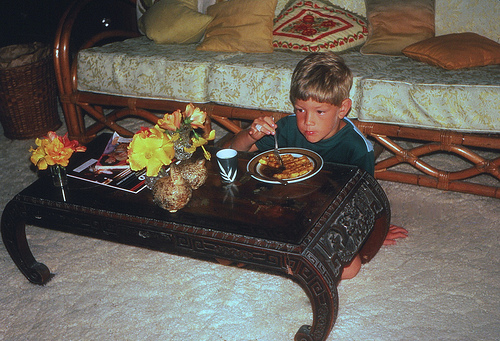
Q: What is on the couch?
A: Pillows.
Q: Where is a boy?
A: Sitting on floor.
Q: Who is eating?
A: A boy.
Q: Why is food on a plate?
A: To be eaten.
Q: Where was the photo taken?
A: In a living room.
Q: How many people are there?
A: One.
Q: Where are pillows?
A: On a couch.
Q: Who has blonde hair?
A: Boy.